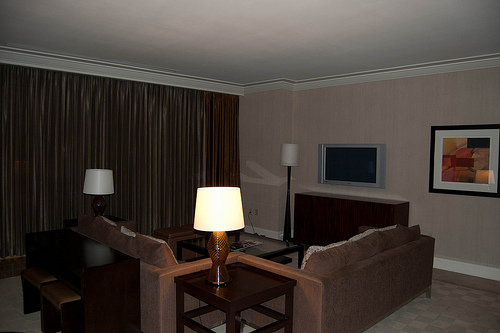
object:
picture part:
[435, 132, 447, 151]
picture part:
[463, 131, 492, 156]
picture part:
[465, 154, 499, 183]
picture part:
[433, 166, 447, 188]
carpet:
[361, 281, 500, 333]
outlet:
[249, 208, 253, 214]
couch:
[237, 221, 435, 333]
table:
[24, 228, 141, 333]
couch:
[75, 216, 244, 333]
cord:
[248, 212, 256, 233]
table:
[177, 232, 305, 269]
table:
[173, 259, 297, 331]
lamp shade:
[82, 168, 115, 195]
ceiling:
[0, 4, 499, 80]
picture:
[440, 137, 491, 184]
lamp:
[277, 142, 300, 167]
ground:
[0, 275, 500, 333]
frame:
[428, 124, 500, 199]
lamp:
[192, 186, 244, 233]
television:
[316, 139, 387, 188]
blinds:
[0, 62, 241, 257]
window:
[0, 69, 239, 245]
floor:
[359, 280, 497, 333]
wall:
[248, 84, 489, 272]